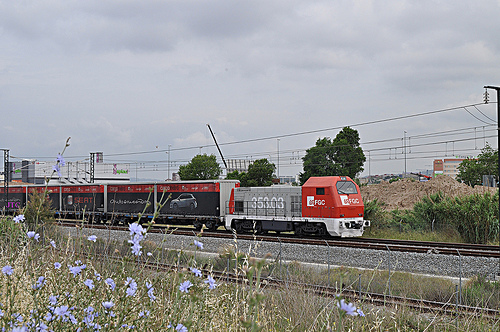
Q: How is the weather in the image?
A: It is overcast.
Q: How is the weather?
A: It is overcast.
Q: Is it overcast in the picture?
A: Yes, it is overcast.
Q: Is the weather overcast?
A: Yes, it is overcast.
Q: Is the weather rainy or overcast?
A: It is overcast.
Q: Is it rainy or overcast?
A: It is overcast.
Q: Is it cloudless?
A: No, it is overcast.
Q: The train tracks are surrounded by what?
A: The train tracks are surrounded by the rocks.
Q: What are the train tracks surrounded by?
A: The train tracks are surrounded by the rocks.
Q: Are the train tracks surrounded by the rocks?
A: Yes, the train tracks are surrounded by the rocks.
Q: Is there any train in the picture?
A: Yes, there is a train.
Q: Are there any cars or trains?
A: Yes, there is a train.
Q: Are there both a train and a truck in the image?
A: No, there is a train but no trucks.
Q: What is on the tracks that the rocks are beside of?
A: The train is on the train tracks.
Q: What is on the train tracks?
A: The train is on the train tracks.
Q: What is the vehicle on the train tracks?
A: The vehicle is a train.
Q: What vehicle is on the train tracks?
A: The vehicle is a train.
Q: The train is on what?
A: The train is on the tracks.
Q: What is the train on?
A: The train is on the tracks.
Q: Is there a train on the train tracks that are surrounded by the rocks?
A: Yes, there is a train on the railroad tracks.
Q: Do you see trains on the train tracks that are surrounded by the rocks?
A: Yes, there is a train on the railroad tracks.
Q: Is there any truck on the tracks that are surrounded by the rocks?
A: No, there is a train on the tracks.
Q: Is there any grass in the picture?
A: Yes, there is grass.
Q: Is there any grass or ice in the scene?
A: Yes, there is grass.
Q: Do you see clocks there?
A: No, there are no clocks.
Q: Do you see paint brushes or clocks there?
A: No, there are no clocks or paint brushes.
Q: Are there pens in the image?
A: No, there are no pens.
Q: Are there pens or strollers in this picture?
A: No, there are no pens or strollers.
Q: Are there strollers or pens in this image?
A: No, there are no pens or strollers.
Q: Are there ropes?
A: No, there are no ropes.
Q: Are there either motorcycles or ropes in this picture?
A: No, there are no ropes or motorcycles.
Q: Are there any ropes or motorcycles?
A: No, there are no ropes or motorcycles.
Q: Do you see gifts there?
A: No, there are no gifts.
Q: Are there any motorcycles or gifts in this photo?
A: No, there are no gifts or motorcycles.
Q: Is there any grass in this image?
A: Yes, there is grass.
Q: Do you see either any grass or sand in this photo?
A: Yes, there is grass.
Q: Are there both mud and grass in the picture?
A: No, there is grass but no mud.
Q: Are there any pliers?
A: No, there are no pliers.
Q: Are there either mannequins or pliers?
A: No, there are no pliers or mannequins.